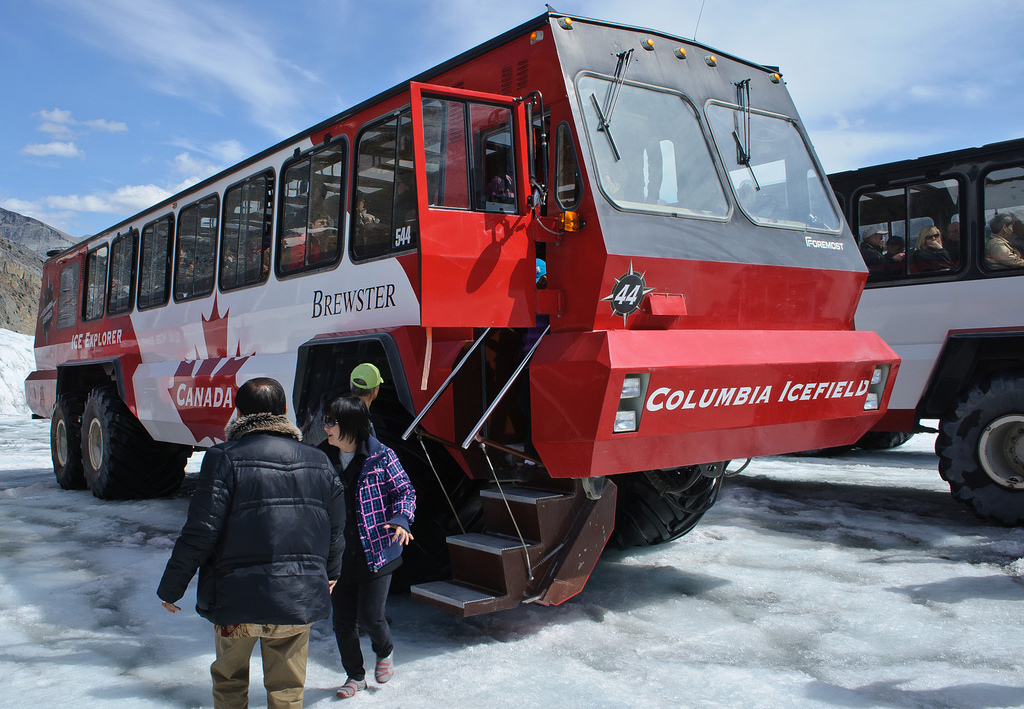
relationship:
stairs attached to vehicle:
[408, 463, 619, 636] [25, 11, 903, 631]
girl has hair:
[316, 394, 421, 703] [321, 398, 373, 455]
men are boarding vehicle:
[156, 375, 344, 708] [25, 11, 903, 631]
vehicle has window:
[25, 11, 903, 631] [349, 105, 422, 270]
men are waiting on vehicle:
[156, 375, 344, 708] [25, 11, 903, 631]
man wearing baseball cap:
[342, 360, 387, 413] [346, 361, 384, 391]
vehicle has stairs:
[25, 11, 903, 631] [408, 463, 619, 636]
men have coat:
[156, 375, 344, 708] [156, 415, 348, 628]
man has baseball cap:
[342, 360, 387, 413] [346, 361, 384, 391]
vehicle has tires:
[25, 11, 903, 631] [77, 388, 189, 507]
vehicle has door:
[25, 11, 903, 631] [408, 78, 537, 340]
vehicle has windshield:
[25, 11, 903, 631] [572, 67, 849, 243]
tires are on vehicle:
[77, 388, 189, 507] [25, 11, 903, 631]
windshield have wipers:
[572, 67, 849, 243] [590, 48, 646, 160]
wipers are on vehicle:
[590, 48, 646, 160] [25, 11, 903, 631]